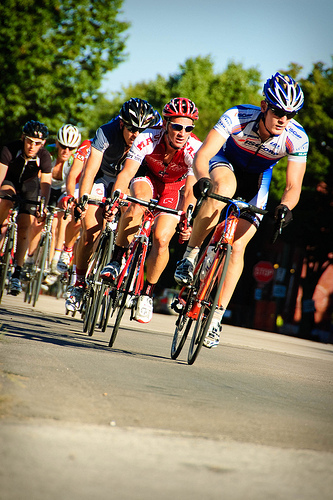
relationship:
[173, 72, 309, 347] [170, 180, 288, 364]
racer on bike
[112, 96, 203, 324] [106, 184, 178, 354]
bike racer on bike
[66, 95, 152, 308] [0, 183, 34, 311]
racer on bike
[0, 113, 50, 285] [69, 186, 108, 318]
racer on bike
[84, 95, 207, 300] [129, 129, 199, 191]
racer wears shirt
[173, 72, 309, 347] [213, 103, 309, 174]
racer wears shirt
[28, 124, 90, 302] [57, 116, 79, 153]
bike racer wears safety helmet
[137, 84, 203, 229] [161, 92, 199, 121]
bike racer wears helmet